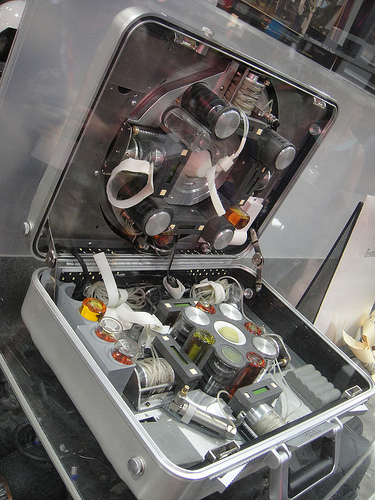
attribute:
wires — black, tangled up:
[8, 416, 66, 457]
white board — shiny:
[325, 218, 374, 342]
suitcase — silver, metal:
[16, 4, 373, 499]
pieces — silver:
[193, 310, 283, 392]